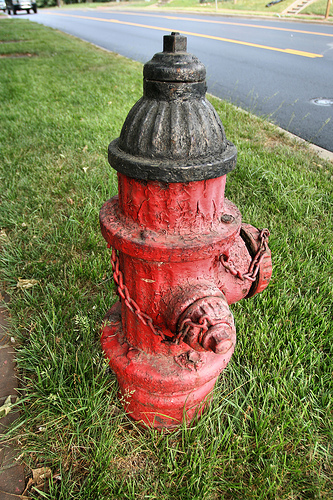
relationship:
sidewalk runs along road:
[123, 1, 320, 19] [4, 6, 331, 149]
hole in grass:
[5, 48, 38, 60] [4, 32, 331, 496]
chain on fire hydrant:
[109, 246, 208, 352] [93, 20, 273, 437]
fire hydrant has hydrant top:
[93, 20, 273, 437] [103, 18, 242, 188]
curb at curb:
[258, 109, 299, 162] [258, 109, 299, 162]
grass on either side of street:
[4, 32, 331, 496] [18, 7, 329, 165]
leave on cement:
[12, 271, 38, 296] [0, 310, 47, 497]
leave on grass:
[12, 271, 38, 296] [4, 32, 331, 496]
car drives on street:
[12, 0, 44, 18] [6, 3, 331, 157]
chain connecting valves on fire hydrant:
[100, 241, 285, 372] [97, 29, 274, 426]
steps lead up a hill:
[281, 5, 312, 20] [103, 0, 329, 23]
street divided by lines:
[29, 9, 330, 148] [57, 4, 328, 64]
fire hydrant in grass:
[97, 29, 274, 426] [4, 32, 331, 496]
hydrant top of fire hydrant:
[103, 18, 242, 188] [97, 29, 274, 426]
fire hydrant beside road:
[97, 29, 274, 426] [4, 6, 331, 149]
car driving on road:
[2, 0, 41, 20] [4, 6, 331, 149]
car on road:
[2, 0, 41, 20] [44, 7, 175, 36]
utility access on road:
[306, 89, 331, 107] [212, 25, 327, 86]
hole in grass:
[0, 43, 38, 64] [4, 32, 331, 496]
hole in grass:
[2, 39, 26, 42] [4, 32, 331, 496]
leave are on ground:
[14, 276, 38, 291] [1, 16, 321, 497]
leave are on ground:
[1, 392, 20, 413] [1, 16, 321, 497]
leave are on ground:
[21, 465, 54, 495] [1, 16, 321, 497]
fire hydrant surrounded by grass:
[93, 20, 273, 437] [5, 113, 321, 478]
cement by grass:
[12, 325, 56, 475] [24, 262, 279, 452]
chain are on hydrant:
[109, 246, 208, 350] [78, 29, 274, 426]